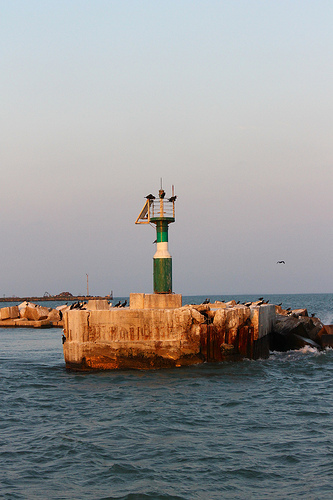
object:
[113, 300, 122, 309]
bird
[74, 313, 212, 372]
rock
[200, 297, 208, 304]
bird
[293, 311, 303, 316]
bird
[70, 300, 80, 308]
bird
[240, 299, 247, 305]
bird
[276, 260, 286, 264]
bird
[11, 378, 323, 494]
water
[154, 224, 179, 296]
structure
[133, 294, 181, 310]
base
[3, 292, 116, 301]
ship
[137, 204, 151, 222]
instrument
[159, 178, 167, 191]
antennae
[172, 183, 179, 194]
antennae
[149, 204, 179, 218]
railing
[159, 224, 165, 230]
top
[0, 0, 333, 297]
sky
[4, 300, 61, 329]
rock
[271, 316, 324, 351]
rock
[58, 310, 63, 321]
bird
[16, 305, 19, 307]
bird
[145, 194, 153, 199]
bird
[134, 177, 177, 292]
buoy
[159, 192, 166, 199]
bird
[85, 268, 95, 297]
crane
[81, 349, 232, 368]
stains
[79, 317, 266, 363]
wall